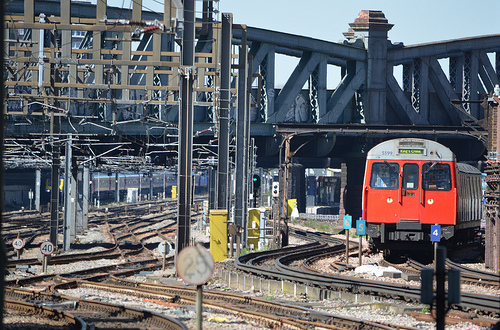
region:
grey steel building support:
[307, 59, 327, 120]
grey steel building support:
[327, 72, 360, 117]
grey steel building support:
[272, 52, 312, 117]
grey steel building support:
[387, 76, 420, 122]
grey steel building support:
[411, 63, 430, 123]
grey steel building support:
[427, 61, 464, 123]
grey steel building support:
[462, 57, 481, 114]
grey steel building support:
[235, 44, 245, 251]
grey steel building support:
[215, 44, 227, 207]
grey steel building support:
[177, 69, 191, 251]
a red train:
[358, 133, 482, 250]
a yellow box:
[206, 204, 227, 264]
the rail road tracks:
[6, 202, 474, 327]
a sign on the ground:
[178, 243, 213, 328]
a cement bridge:
[16, 0, 496, 150]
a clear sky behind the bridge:
[253, 12, 346, 32]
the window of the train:
[370, 161, 397, 186]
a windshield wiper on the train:
[424, 161, 437, 177]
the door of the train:
[398, 162, 416, 219]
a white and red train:
[358, 139, 488, 241]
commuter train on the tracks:
[363, 128, 479, 259]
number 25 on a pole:
[171, 238, 219, 289]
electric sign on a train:
[396, 141, 431, 157]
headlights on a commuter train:
[383, 193, 395, 206]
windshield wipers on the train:
[416, 157, 439, 181]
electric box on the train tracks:
[208, 203, 230, 259]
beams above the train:
[270, 38, 447, 123]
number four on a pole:
[428, 218, 447, 242]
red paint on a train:
[351, 152, 456, 234]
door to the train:
[397, 154, 424, 225]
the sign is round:
[160, 240, 225, 286]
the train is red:
[366, 133, 491, 249]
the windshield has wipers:
[370, 160, 454, 193]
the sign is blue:
[425, 224, 443, 243]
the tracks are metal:
[251, 241, 312, 281]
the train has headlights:
[382, 191, 441, 211]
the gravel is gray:
[63, 261, 91, 269]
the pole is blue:
[259, 203, 273, 244]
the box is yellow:
[207, 209, 231, 261]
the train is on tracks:
[365, 118, 498, 284]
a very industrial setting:
[50, 19, 290, 281]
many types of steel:
[56, 3, 338, 278]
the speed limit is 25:
[166, 226, 252, 298]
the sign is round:
[141, 229, 243, 302]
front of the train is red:
[316, 111, 484, 321]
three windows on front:
[334, 127, 478, 317]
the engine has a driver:
[343, 104, 493, 267]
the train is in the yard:
[18, 23, 489, 300]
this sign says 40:
[31, 239, 101, 291]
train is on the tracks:
[307, 89, 493, 284]